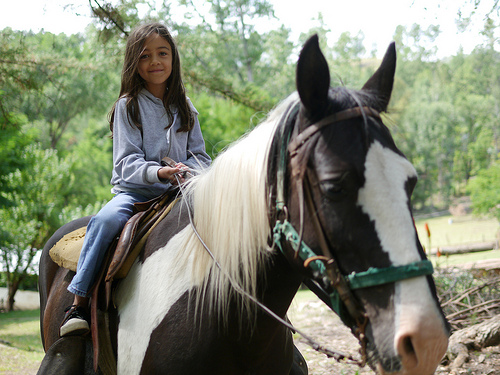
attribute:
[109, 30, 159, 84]
hair — long, dark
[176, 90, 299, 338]
mane — white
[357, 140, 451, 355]
stripe — white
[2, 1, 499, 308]
trees — green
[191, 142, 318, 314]
hair — blonde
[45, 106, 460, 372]
horse — brown, white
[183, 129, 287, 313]
blond mane — blonde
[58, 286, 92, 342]
shoe — child's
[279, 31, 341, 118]
ears — brown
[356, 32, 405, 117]
ears — brown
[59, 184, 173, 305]
pants — blue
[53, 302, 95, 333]
b&w shoes — black, white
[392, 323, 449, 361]
nose — white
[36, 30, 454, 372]
horse — dark brown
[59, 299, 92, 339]
shoes — black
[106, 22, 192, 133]
hair — long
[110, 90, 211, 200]
shirt — gray